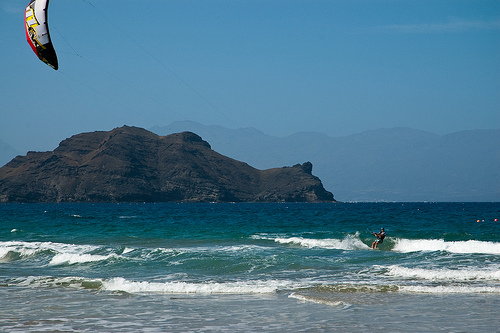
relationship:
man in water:
[370, 226, 387, 253] [0, 203, 500, 330]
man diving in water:
[370, 226, 387, 253] [0, 203, 500, 330]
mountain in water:
[1, 124, 336, 202] [0, 203, 498, 332]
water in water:
[0, 203, 500, 330] [0, 203, 498, 332]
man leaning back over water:
[370, 226, 387, 253] [0, 203, 500, 330]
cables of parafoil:
[59, 0, 369, 236] [23, 1, 63, 71]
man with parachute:
[362, 226, 397, 253] [14, 2, 84, 70]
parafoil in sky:
[23, 2, 58, 66] [0, 0, 498, 156]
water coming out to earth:
[0, 203, 498, 332] [21, 111, 474, 325]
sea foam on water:
[30, 240, 287, 301] [0, 203, 500, 330]